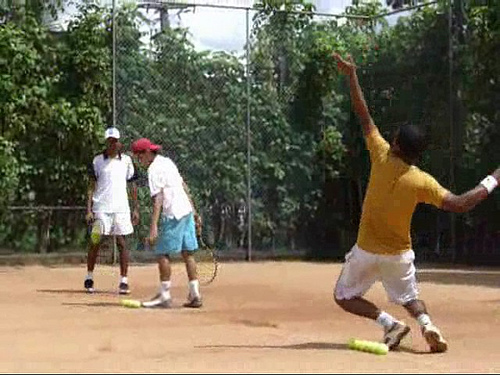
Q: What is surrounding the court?
A: Fence.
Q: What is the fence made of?
A: Metal mesh.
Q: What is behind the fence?
A: Trees.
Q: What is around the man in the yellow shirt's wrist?
A: Sweatband.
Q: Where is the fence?
A: Around the court.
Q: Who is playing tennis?
A: The man.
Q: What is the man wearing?
A: White color shorts.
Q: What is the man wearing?
A: A yellow color t shirt.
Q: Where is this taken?
A: Tennis court.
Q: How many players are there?
A: 3.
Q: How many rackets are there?
A: 2.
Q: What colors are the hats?
A: Red and white.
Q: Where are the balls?
A: On the ground.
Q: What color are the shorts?
A: White and blue.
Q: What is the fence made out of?
A: Metal.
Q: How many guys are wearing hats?
A: 2.